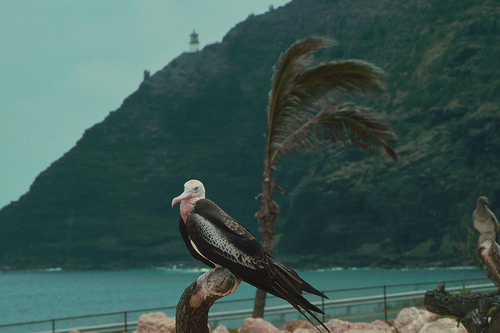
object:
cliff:
[26, 11, 497, 236]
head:
[462, 193, 496, 231]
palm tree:
[250, 28, 398, 318]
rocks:
[120, 292, 476, 331]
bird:
[165, 175, 307, 295]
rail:
[18, 279, 499, 331]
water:
[0, 272, 391, 308]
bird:
[468, 194, 499, 242]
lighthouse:
[167, 21, 214, 66]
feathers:
[153, 210, 305, 297]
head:
[168, 177, 208, 219]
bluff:
[149, 41, 231, 96]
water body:
[0, 269, 494, 331]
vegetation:
[0, 7, 498, 267]